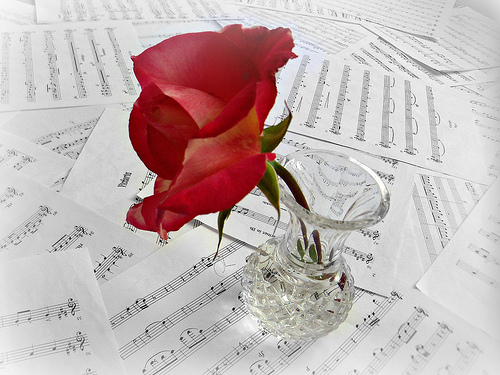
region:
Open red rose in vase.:
[80, 20, 427, 353]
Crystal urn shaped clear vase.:
[236, 126, 393, 366]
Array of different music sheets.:
[245, 15, 498, 170]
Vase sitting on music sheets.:
[214, 133, 383, 374]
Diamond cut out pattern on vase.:
[230, 243, 374, 353]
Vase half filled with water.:
[228, 184, 380, 366]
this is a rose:
[52, 29, 414, 306]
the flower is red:
[93, 38, 257, 245]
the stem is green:
[256, 153, 356, 273]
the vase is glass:
[220, 239, 437, 355]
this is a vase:
[207, 177, 369, 337]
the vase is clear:
[206, 216, 324, 353]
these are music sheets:
[22, 144, 189, 333]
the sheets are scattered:
[57, 126, 457, 329]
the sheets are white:
[42, 200, 255, 335]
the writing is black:
[314, 85, 455, 213]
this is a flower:
[61, 24, 454, 345]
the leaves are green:
[237, 118, 301, 209]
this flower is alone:
[192, 161, 386, 318]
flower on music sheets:
[44, 71, 388, 313]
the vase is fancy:
[270, 207, 410, 329]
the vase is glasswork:
[240, 187, 405, 321]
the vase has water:
[98, 167, 458, 347]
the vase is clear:
[264, 188, 419, 347]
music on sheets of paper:
[1, 2, 498, 372]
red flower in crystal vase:
[127, 22, 390, 337]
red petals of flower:
[125, 23, 294, 239]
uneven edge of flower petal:
[226, 27, 299, 119]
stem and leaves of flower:
[216, 109, 320, 270]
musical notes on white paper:
[117, 278, 230, 353]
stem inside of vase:
[241, 148, 388, 349]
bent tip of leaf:
[263, 100, 293, 150]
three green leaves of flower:
[208, 99, 297, 258]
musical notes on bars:
[108, 261, 240, 373]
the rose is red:
[112, 32, 306, 232]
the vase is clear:
[248, 146, 365, 351]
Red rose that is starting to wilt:
[102, 22, 312, 263]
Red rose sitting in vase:
[3, 2, 496, 372]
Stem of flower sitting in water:
[278, 162, 348, 339]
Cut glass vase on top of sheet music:
[240, 147, 390, 337]